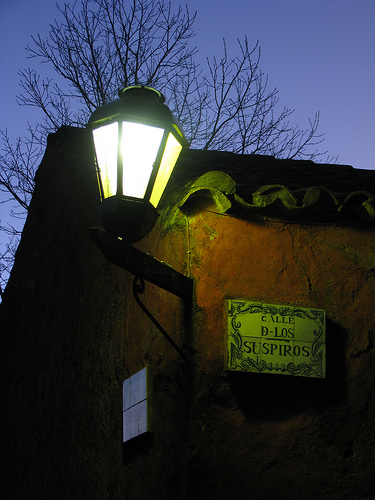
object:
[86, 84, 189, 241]
light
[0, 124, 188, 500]
wall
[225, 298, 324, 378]
sign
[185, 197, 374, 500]
wall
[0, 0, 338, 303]
tree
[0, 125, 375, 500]
building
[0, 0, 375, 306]
sky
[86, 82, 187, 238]
frame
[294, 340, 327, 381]
tile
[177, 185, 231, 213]
shingles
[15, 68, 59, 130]
branches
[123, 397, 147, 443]
window